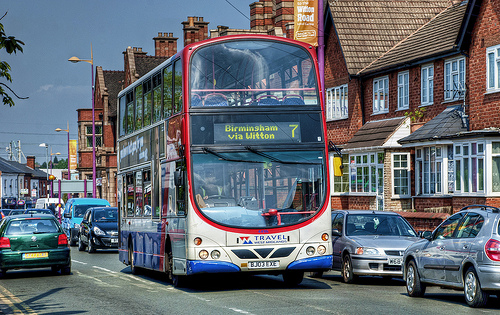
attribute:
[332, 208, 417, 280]
car — silver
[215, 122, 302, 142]
sign — yellow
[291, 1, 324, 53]
sign — orange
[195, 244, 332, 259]
headlights — small, round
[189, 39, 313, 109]
window — glass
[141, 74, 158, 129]
window — glass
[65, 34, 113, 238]
pole — tall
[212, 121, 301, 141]
sign — digital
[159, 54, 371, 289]
bus — red, white, blue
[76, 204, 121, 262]
car — black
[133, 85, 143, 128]
window — glass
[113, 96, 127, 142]
window — glass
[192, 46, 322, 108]
window — glass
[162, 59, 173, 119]
window — glass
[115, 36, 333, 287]
bus — double decker, double-decker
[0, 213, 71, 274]
car — small, green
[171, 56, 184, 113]
window — glass